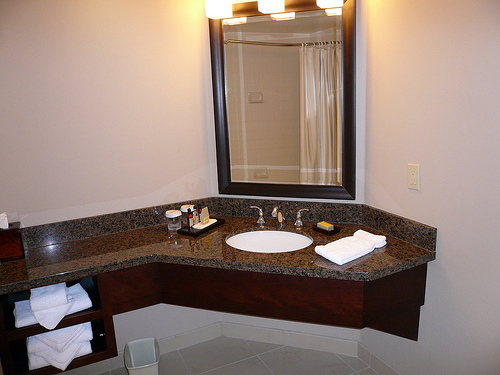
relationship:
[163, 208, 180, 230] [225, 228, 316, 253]
glass by sink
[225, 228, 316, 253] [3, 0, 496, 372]
sink in bathroom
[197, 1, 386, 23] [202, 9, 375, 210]
lights over mirror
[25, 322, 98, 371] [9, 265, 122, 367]
towels on shelf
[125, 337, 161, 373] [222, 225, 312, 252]
garbage can under sink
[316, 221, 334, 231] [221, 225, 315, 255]
soap on sink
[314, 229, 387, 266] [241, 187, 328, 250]
towel on sink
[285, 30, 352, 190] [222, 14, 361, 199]
curtain in mirror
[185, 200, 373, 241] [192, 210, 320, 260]
facets and sprout on sink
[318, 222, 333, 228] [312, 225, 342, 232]
soap in a dish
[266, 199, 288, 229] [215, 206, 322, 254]
water faucet on a sink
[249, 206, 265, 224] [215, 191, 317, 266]
faucet on a sink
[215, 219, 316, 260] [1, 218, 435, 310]
bowl in countertop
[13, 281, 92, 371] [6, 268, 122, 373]
towels on shelf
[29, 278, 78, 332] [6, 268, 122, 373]
towels on shelf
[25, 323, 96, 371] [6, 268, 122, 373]
towels on shelf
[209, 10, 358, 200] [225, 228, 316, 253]
mirror above sink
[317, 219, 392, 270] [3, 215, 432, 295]
towel on counter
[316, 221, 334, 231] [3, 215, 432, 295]
soap on counter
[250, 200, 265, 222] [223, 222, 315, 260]
faucet for sink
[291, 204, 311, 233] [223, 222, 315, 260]
faucet for sink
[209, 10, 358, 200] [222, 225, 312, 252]
mirror over sink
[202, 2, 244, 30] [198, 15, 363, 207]
light fixture over mirror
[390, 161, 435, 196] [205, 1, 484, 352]
outlet on wall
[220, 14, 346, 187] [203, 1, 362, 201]
mirror in mirror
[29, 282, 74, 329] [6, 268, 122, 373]
towels on shelf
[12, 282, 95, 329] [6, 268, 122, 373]
towels on shelf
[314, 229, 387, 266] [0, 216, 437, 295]
towel on counter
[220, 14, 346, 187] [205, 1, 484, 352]
mirror on wall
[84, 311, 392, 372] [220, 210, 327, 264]
baseboard below sink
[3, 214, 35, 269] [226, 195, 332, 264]
box on sink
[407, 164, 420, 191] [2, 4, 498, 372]
outlet on wall